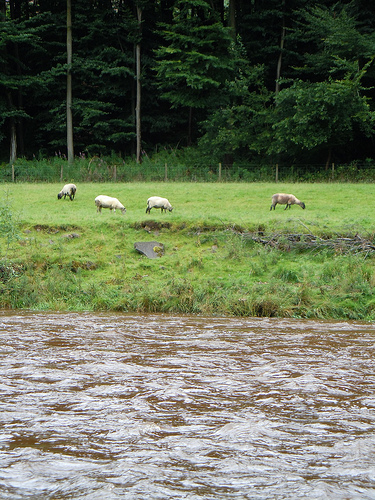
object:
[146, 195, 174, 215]
sheep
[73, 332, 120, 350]
river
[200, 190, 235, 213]
grass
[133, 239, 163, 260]
rock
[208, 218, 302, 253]
twigs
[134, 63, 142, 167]
trunk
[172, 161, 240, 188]
fence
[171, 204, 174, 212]
head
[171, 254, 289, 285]
field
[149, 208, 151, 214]
leg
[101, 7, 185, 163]
tree